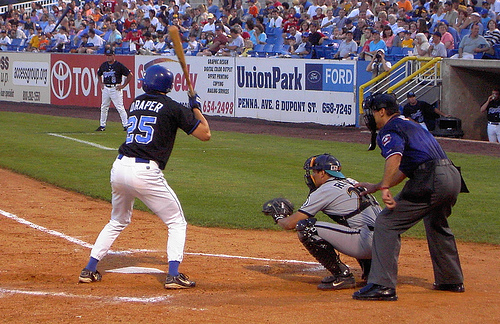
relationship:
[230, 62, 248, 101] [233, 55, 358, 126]
blue ketter on board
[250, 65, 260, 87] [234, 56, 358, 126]
blue letter on board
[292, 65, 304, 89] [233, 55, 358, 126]
letter on board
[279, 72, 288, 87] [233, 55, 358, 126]
letter on board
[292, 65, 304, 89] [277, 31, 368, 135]
letter on board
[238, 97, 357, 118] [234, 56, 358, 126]
blue letter on board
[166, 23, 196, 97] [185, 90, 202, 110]
wooden bat in batters hand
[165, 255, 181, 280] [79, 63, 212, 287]
blue socks on man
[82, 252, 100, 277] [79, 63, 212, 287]
blue socks on man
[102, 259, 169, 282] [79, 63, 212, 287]
plate under man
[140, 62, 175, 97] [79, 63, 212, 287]
blue helmet on man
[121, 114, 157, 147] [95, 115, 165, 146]
25 on table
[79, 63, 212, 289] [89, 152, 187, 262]
man wears pants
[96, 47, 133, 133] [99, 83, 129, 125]
man wears pants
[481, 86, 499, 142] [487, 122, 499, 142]
man wears pants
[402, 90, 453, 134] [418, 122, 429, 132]
man wears pants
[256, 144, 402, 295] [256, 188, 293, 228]
man holding mitt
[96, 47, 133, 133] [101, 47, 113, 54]
man wears cap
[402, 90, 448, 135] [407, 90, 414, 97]
man wears cap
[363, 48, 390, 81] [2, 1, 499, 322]
man taking pictures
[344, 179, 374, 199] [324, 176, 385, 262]
hand on back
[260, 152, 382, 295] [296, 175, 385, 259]
man wearing uniform